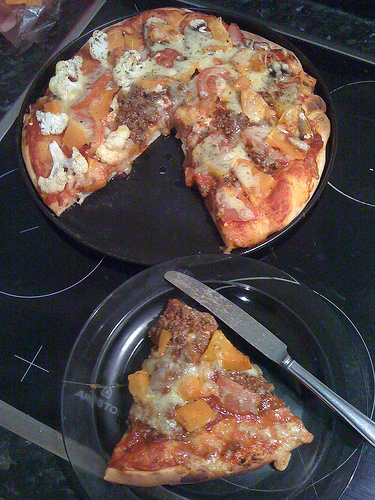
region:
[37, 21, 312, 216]
pizza on a black tray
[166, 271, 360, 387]
silver knife on plate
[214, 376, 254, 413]
red tomato on plate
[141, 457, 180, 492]
brown crust of pizza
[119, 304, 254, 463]
triangular slice of pizza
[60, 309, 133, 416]
clear plate on black table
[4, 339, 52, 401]
an ex on the table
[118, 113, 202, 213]
slive missing from pizza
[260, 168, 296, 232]
red sauce on pizza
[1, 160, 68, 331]
white circle on table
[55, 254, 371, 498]
a clear plate that is full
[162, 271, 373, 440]
a silver metal dirty knife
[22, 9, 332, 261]
a plate stone pizza plate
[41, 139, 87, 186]
a piece of white cauliflower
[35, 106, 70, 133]
a piece of white cauliflower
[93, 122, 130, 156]
a piece of white cauliflower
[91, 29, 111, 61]
a piece of white cauliflower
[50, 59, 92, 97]
a piece of white cauliflower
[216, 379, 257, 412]
a red tomato slice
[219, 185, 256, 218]
a red tomato slice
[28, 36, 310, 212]
Pizza is in plate.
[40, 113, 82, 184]
Cauliflower is white color.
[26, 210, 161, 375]
Plates are in tray.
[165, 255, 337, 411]
Knife is in plate.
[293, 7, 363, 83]
Tray is in counter.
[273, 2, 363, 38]
Counter is black color.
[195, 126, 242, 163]
Cheese is white color.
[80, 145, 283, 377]
Two plates are in tray.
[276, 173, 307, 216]
Bread is brown color.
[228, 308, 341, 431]
Knife is silver color.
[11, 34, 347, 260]
a homemade pizza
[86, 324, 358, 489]
a slice of homemade pizza on a plate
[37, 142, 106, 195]
cauliflower on a homemade pizza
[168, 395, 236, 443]
yellow bell pepper on a homemade pizza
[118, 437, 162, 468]
tomato sauce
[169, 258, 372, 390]
a table knife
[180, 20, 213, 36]
a mushroom on a homemade pizza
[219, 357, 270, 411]
a tomato slice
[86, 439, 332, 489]
pizza crust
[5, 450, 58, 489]
granite countertop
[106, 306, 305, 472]
one slice of pizza with tomatoes and sausage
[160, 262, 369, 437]
used knife sitting on a plate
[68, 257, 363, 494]
black circular plate with pizza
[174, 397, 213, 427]
chunk of orange tomato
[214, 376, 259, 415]
chunk of red tomato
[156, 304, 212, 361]
chunk of sausage on pizza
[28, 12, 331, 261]
pizza with only one slice missing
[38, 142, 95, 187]
cooked cauliflower on pizza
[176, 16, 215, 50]
slice of cooked mushroom on pizza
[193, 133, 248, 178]
melted cheese on pizza